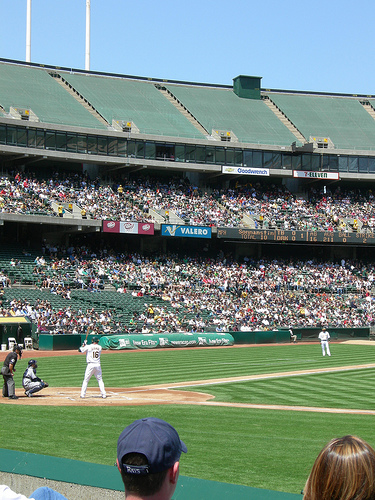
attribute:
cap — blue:
[104, 413, 193, 473]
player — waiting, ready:
[67, 320, 113, 401]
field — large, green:
[5, 331, 374, 477]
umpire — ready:
[0, 335, 27, 403]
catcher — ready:
[16, 356, 56, 404]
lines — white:
[113, 382, 219, 406]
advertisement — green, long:
[97, 326, 233, 350]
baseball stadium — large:
[4, 57, 364, 356]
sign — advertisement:
[157, 221, 216, 244]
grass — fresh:
[132, 358, 344, 446]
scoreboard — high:
[216, 220, 374, 247]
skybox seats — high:
[6, 59, 370, 178]